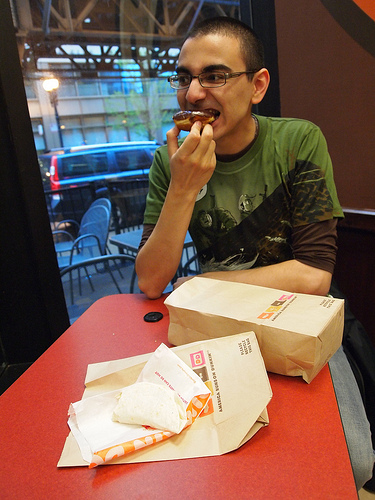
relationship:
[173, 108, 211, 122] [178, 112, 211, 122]
chocolate covered chocolate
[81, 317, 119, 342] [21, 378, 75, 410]
red table top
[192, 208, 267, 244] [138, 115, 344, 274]
design on boys shirt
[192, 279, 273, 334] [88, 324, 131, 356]
brown bags on table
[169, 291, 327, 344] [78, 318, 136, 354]
paper bags on table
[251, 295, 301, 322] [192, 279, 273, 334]
design on bag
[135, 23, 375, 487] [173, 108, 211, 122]
boy is eating chocolate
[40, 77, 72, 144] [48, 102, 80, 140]
street light  on pole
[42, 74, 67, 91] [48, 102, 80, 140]
light on black pole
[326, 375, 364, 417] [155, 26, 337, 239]
pants leg on man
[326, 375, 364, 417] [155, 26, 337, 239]
pants grey on man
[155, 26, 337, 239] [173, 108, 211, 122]
boy is eating a chocolate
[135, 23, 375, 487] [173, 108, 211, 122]
boy is eating a chocolate chocolate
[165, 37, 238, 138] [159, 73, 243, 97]
boy is wearing glasses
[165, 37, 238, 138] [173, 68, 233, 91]
boy is wearing clear glasses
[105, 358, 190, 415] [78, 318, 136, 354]
napkins on table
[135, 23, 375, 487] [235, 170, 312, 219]
boy is shirt boys shirt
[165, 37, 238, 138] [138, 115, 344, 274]
boy is wearing a boys shirt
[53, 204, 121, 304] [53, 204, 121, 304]
chairs outside chairs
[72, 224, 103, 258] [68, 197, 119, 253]
arm handle on chair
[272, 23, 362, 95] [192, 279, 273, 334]
wall dark brown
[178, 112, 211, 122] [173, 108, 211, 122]
chocolate glazed chocolate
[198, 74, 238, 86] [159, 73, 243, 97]
black rimmed glasses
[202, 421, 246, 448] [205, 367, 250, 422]
flat duncan donuts bag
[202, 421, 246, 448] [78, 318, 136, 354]
flat paper bag on table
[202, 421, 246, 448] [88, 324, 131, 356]
flat bag on table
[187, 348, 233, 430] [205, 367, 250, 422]
duncan donut paper bag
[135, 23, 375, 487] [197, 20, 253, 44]
boy is has short hair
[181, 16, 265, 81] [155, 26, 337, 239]
hair cut on man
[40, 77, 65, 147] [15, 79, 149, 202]
street through window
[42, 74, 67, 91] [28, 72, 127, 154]
light on lamp through window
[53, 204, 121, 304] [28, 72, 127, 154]
chairs furniture through window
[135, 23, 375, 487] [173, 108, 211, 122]
boy is eating a brown chocolate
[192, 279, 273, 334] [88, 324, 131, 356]
brown napkins on table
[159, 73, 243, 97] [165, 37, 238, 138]
man is wearing glasses on face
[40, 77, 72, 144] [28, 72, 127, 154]
streetlight is tall and outside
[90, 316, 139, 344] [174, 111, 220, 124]
table in a dunking donuts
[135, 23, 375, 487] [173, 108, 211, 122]
boy is eating a donught chocolate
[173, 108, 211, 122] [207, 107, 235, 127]
chocolate donught man eating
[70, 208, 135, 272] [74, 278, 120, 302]
chairs are outside on the patio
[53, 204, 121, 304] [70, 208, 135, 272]
chairs are outside chairs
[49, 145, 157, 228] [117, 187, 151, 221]
car outside on street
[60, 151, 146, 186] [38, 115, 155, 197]
car blue and parked outside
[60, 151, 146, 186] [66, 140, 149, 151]
car parked and has light on it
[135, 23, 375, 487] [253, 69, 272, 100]
boy is has a left ear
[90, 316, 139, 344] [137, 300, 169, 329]
table has an object on it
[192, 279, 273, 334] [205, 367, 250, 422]
brown paper bag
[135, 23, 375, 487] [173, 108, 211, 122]
boy is eating a round chocolate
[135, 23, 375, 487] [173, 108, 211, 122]
boy is has a chocolate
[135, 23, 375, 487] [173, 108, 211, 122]
boy is eating a chocolate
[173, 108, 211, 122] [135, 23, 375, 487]
chocolate being eaten boy is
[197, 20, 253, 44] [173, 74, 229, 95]
short hair man wearing glasses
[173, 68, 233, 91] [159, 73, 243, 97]
man is looking through h glasses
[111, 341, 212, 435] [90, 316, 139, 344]
napkins on table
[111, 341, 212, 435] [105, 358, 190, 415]
napkins that brown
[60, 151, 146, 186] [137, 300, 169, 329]
suv has light on it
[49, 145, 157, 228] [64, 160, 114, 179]
car has windows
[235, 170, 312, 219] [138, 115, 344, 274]
man wearing a boys shirt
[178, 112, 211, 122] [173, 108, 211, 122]
chocolate on chocolate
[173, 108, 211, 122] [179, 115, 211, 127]
chocolate has chocolate on it